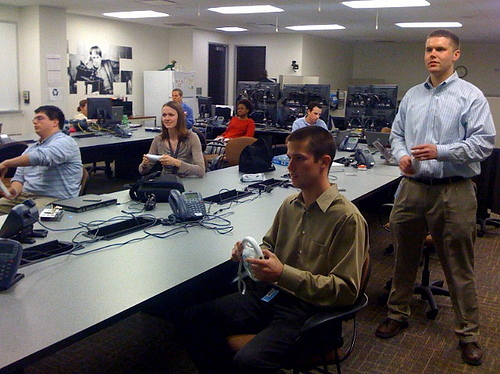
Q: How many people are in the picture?
A: 8.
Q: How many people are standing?
A: One.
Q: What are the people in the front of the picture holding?
A: Game controllers.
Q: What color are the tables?
A: Gray.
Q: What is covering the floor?
A: Carpet.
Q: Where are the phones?
A: On the tables.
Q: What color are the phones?
A: Black.